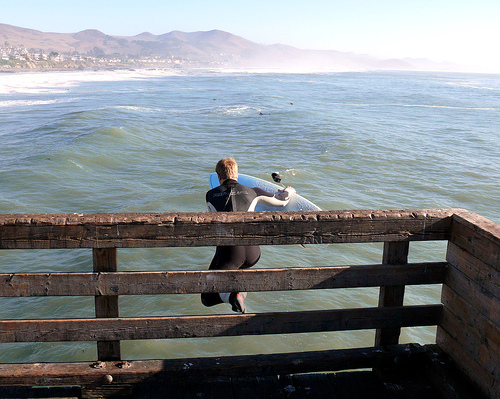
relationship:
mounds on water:
[0, 70, 497, 361] [346, 99, 433, 155]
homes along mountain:
[22, 56, 189, 72] [53, 21, 318, 74]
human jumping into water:
[200, 157, 296, 314] [72, 94, 361, 162]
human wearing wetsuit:
[200, 157, 296, 314] [202, 180, 298, 310]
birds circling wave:
[187, 82, 314, 118] [2, 77, 179, 266]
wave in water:
[75, 102, 194, 115] [1, 71, 497, 363]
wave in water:
[213, 102, 256, 117] [1, 71, 497, 363]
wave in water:
[1, 95, 73, 108] [1, 71, 497, 363]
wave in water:
[1, 66, 260, 93] [1, 71, 497, 363]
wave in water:
[437, 75, 499, 94] [1, 71, 497, 363]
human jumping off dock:
[200, 157, 296, 314] [1, 196, 498, 386]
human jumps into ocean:
[200, 157, 296, 314] [283, 75, 393, 155]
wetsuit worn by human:
[208, 190, 264, 300] [205, 152, 262, 315]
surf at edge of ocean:
[5, 65, 359, 82] [51, 81, 441, 171]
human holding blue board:
[200, 157, 296, 314] [207, 170, 322, 211]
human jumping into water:
[200, 157, 296, 314] [0, 70, 499, 397]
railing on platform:
[0, 208, 499, 399] [28, 377, 468, 396]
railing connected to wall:
[357, 207, 435, 249] [432, 202, 488, 391]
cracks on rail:
[25, 224, 474, 237] [0, 208, 450, 246]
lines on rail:
[47, 227, 450, 243] [0, 208, 450, 246]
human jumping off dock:
[200, 157, 296, 314] [1, 207, 499, 398]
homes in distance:
[0, 53, 180, 66] [3, 15, 314, 115]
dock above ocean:
[1, 196, 498, 386] [0, 68, 499, 390]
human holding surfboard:
[200, 157, 296, 314] [199, 163, 324, 232]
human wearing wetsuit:
[200, 157, 296, 314] [199, 177, 293, 313]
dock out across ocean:
[1, 207, 499, 398] [3, 58, 495, 344]